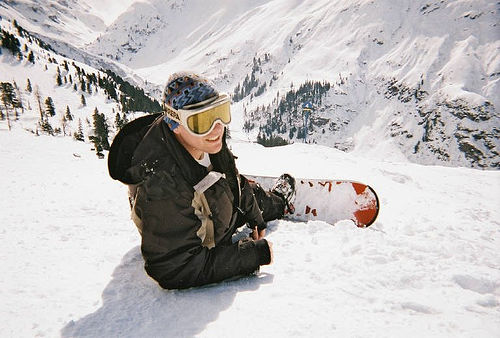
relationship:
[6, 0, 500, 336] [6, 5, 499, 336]
mountains have snow.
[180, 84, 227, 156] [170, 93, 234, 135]
face with goggles.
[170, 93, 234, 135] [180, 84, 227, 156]
goggles. on face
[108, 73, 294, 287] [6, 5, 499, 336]
man on snow.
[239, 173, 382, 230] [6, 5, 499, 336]
snowboard on snow.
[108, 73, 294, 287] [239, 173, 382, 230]
man has snowboard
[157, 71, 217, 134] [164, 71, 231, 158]
hat on head.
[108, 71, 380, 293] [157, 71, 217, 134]
snowboarder wearing hat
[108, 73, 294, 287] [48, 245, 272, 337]
man cast shadow.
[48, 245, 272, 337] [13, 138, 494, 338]
shadow. on ground.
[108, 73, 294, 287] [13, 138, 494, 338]
man on ground.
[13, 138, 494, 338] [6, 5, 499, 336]
ground has snow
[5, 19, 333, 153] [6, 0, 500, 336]
trees on mountain.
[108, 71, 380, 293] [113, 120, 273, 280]
snowboarder wears jacket.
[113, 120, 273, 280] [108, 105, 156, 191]
jacket has hood.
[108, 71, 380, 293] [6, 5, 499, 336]
snowboarder in snow.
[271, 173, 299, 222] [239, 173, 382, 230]
boot on snowboard.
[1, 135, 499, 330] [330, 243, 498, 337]
snow has footprints.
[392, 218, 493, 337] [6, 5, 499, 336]
footprints in snow.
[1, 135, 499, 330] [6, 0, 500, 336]
snow on mountain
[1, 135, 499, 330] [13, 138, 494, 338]
snow on ground.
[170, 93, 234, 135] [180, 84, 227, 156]
goggles on face.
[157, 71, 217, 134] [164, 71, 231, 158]
hat on head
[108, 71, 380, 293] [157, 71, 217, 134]
snowboarder wears hat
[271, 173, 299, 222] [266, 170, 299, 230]
boot on foot.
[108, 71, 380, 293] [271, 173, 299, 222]
snowboarder wearing boot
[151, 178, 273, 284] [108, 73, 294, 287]
sleeve on coat.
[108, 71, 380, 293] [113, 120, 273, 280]
snowboarder wears coat.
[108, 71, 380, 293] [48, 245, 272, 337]
snowboarder has shadow.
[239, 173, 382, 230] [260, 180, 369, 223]
snowboard has snow.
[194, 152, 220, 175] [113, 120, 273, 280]
shirt under coat.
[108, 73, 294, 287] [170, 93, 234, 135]
man wearing goggles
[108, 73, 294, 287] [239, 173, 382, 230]
man on snowboard.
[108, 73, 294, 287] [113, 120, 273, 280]
man wears jacket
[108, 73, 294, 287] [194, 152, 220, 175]
man wears shirt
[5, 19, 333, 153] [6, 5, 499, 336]
trees in snow.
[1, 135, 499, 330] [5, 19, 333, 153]
snow has trees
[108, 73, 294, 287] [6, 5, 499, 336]
man in snow.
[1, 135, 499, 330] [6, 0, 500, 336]
snow on mountains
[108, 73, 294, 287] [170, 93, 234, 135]
man wears goggles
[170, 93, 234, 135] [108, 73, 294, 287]
goggles on man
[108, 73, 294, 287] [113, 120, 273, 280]
man wearing jacket.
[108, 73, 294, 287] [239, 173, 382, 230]
man has snowboard.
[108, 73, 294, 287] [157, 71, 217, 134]
man wears beanie.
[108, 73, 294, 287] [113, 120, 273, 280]
man wears jacket.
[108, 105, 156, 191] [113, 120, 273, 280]
hood on jacket.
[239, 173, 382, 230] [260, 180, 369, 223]
snowboard with snow.